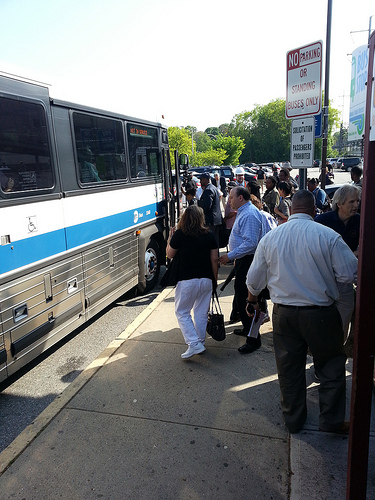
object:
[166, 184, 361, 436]
people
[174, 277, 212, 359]
pants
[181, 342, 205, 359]
shoes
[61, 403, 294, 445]
cracks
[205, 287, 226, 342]
bag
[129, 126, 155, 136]
screen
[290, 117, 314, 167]
post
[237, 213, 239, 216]
button down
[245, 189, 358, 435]
business clothes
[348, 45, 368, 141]
sign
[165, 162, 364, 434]
crowd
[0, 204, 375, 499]
bus stop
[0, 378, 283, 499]
sidewalk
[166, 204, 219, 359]
person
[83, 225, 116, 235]
blue stripe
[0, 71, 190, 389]
bus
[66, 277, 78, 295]
light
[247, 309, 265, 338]
papers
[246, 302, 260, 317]
hand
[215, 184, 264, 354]
man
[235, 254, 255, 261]
belt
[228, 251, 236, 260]
wrist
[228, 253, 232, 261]
watch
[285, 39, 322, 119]
sign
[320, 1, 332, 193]
pole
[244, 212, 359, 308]
shirt